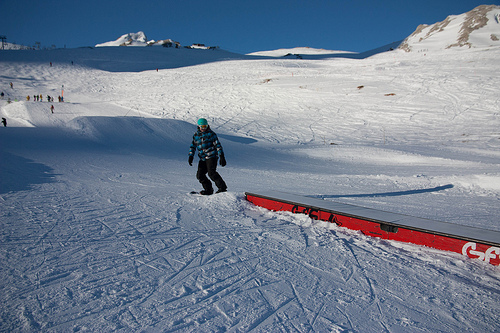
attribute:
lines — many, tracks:
[1, 60, 499, 331]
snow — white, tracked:
[0, 1, 500, 333]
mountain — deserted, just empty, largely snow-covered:
[365, 1, 499, 57]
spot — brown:
[354, 82, 368, 93]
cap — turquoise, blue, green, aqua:
[195, 116, 211, 128]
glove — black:
[187, 154, 195, 168]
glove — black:
[217, 152, 229, 169]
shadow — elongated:
[303, 176, 462, 203]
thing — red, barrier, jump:
[239, 185, 499, 269]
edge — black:
[244, 183, 499, 249]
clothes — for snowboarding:
[190, 124, 226, 189]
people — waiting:
[0, 77, 73, 138]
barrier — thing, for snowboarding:
[238, 183, 499, 270]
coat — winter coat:
[188, 130, 223, 159]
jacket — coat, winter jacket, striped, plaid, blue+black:
[184, 130, 222, 159]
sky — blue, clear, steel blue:
[2, 0, 500, 54]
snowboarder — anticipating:
[180, 115, 235, 203]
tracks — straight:
[3, 187, 498, 332]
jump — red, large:
[242, 183, 499, 272]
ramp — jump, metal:
[245, 183, 499, 279]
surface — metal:
[245, 187, 499, 247]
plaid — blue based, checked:
[187, 130, 224, 158]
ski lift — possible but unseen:
[0, 56, 9, 65]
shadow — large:
[0, 112, 347, 163]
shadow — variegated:
[1, 148, 78, 203]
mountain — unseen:
[1, 49, 6, 60]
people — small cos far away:
[0, 57, 169, 113]